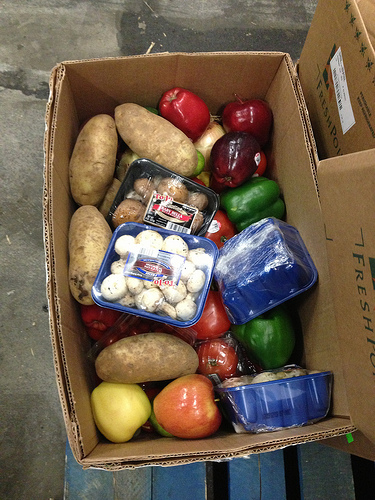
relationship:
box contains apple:
[45, 50, 358, 465] [158, 87, 211, 142]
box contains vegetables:
[45, 50, 358, 465] [66, 99, 317, 431]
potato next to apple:
[115, 103, 202, 169] [160, 89, 212, 135]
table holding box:
[52, 434, 358, 498] [45, 50, 358, 465]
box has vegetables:
[45, 50, 358, 465] [66, 99, 317, 431]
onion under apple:
[192, 120, 228, 153] [160, 89, 212, 135]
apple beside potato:
[160, 89, 212, 135] [115, 103, 202, 169]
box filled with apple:
[45, 50, 358, 465] [158, 87, 211, 142]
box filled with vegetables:
[45, 50, 358, 465] [66, 99, 317, 431]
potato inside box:
[115, 103, 202, 169] [45, 50, 358, 465]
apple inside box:
[160, 89, 212, 135] [45, 50, 358, 465]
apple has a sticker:
[212, 127, 265, 194] [247, 145, 261, 162]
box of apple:
[45, 50, 358, 465] [158, 87, 211, 142]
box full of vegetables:
[45, 50, 358, 465] [66, 99, 317, 431]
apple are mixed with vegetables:
[158, 87, 211, 142] [66, 99, 317, 431]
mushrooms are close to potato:
[94, 218, 218, 316] [115, 103, 202, 169]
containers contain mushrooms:
[100, 159, 315, 330] [94, 218, 218, 316]